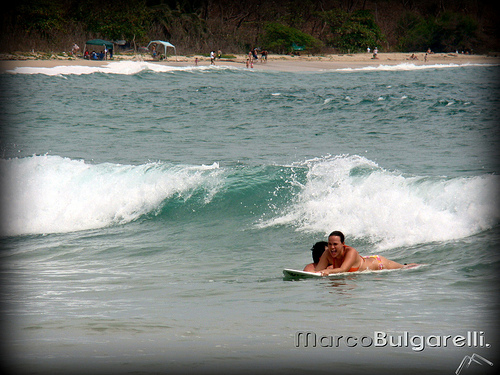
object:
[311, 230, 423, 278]
girl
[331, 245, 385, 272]
bikini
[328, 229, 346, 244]
hair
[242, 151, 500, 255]
wave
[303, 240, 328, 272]
man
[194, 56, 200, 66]
people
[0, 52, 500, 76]
beach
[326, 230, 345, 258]
head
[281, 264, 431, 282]
surfboard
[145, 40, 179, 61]
tent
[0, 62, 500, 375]
water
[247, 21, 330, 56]
trees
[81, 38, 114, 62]
canopy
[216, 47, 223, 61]
people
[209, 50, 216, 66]
people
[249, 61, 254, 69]
people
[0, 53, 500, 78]
shore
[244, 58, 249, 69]
people